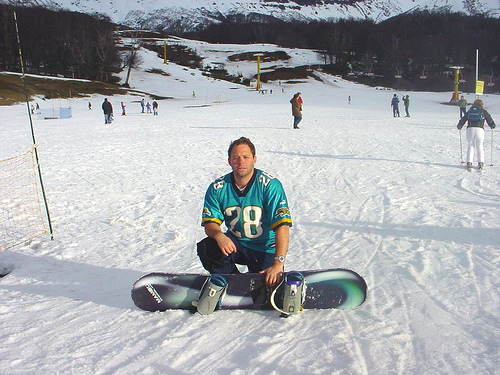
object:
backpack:
[466, 106, 486, 120]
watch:
[274, 256, 286, 263]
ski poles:
[459, 128, 494, 166]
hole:
[34, 99, 71, 119]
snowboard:
[131, 268, 369, 318]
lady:
[457, 99, 496, 169]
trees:
[327, 129, 423, 263]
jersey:
[201, 167, 292, 253]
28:
[224, 205, 264, 238]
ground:
[0, 61, 500, 317]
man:
[195, 136, 292, 285]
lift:
[164, 41, 167, 63]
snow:
[0, 0, 499, 374]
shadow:
[297, 218, 500, 246]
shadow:
[0, 250, 146, 312]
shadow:
[264, 150, 468, 170]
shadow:
[189, 126, 291, 129]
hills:
[0, 0, 499, 97]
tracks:
[301, 174, 500, 317]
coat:
[457, 104, 497, 129]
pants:
[466, 127, 485, 164]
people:
[88, 97, 159, 124]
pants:
[196, 230, 284, 274]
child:
[297, 92, 304, 111]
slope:
[119, 27, 327, 93]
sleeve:
[263, 178, 293, 231]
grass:
[0, 70, 124, 106]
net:
[0, 143, 49, 252]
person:
[290, 94, 302, 129]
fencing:
[12, 12, 56, 241]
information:
[475, 81, 484, 93]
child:
[121, 102, 127, 116]